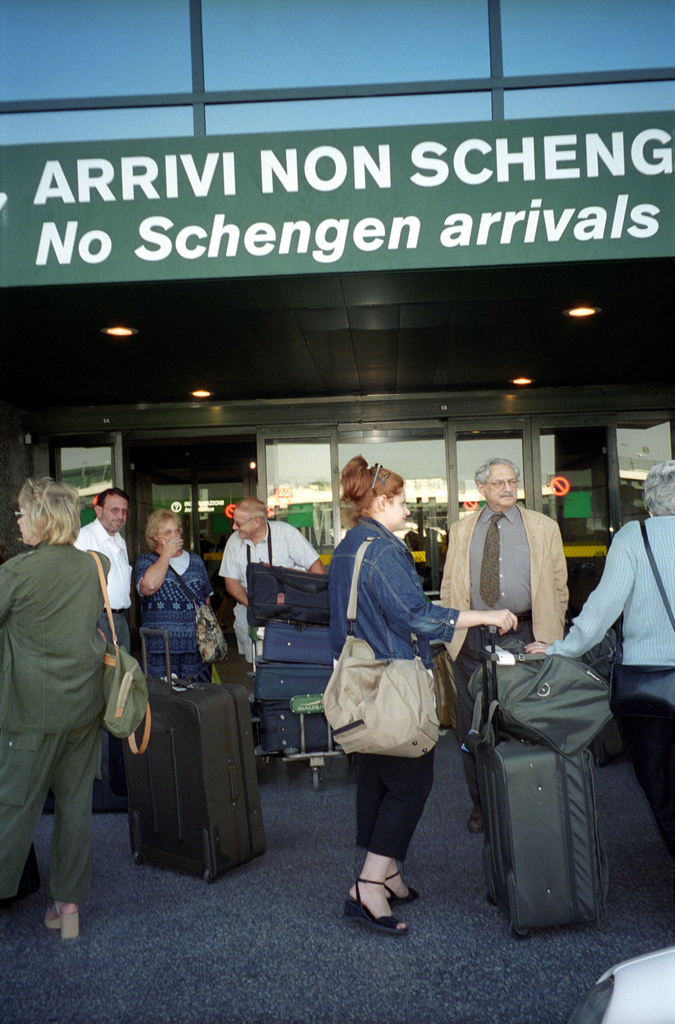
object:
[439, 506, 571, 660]
jacket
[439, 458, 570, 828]
man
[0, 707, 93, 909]
pants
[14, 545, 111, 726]
top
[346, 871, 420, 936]
sandals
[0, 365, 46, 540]
wall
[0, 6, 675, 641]
building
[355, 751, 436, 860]
pants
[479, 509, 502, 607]
tie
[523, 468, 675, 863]
woman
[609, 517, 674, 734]
purse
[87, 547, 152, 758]
bag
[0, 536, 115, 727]
jacket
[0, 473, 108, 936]
woman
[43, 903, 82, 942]
shoes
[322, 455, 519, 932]
woman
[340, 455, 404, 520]
hair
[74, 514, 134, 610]
shirt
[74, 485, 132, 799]
man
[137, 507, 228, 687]
woman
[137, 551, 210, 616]
shirt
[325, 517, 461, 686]
jacket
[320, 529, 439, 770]
bag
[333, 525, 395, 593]
shoulder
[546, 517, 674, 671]
jacket